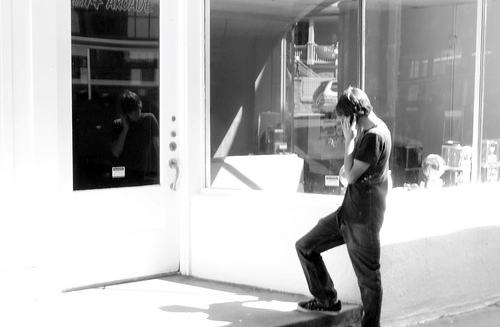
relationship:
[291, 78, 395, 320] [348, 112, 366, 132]
boy with phone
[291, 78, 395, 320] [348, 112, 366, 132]
boy on phone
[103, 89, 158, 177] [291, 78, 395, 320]
reflection of boy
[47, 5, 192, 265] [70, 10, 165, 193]
door has glass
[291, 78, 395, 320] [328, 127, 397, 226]
boy wearing teeshirt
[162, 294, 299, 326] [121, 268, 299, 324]
shadow on ground